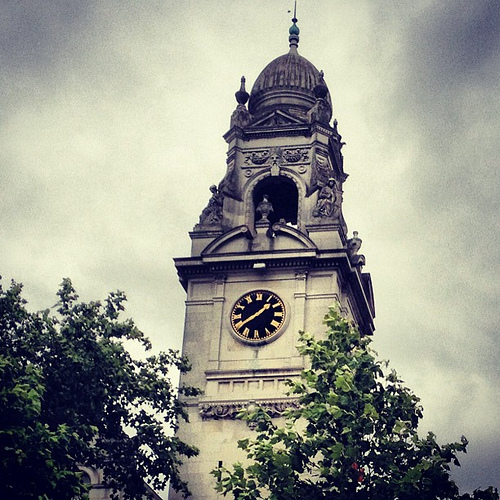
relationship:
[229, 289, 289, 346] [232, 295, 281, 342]
clock has numbers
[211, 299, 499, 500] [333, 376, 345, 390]
tree has leaf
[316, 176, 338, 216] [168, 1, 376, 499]
statue on clock tower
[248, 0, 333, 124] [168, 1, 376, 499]
cathedral roof on clock tower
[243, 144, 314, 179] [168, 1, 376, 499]
engraving on clock tower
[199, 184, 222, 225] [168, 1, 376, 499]
statue on clock tower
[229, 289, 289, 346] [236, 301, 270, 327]
clock has hands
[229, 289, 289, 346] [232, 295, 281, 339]
clock reading 1:39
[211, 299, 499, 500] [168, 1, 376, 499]
tree next to clock tower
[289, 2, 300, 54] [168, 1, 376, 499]
spire on clock tower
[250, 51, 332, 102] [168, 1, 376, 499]
dome atop clock tower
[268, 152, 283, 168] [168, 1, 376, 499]
face carved into clock tower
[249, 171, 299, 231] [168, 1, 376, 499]
arch in clock tower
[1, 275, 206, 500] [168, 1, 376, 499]
tree next to clock tower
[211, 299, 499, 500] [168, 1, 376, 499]
tree in front of clock tower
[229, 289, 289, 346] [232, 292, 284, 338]
clock says 1:39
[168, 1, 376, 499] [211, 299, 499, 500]
clock tower taller than tree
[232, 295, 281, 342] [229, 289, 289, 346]
numbers on clock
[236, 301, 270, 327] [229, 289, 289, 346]
hands of clock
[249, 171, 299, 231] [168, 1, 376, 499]
arch on clock tower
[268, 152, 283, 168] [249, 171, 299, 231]
face above arch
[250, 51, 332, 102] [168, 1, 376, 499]
dome on top of clock tower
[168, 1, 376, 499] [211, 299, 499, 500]
clock tower behind tree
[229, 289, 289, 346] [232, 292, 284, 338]
clock showing 1:39